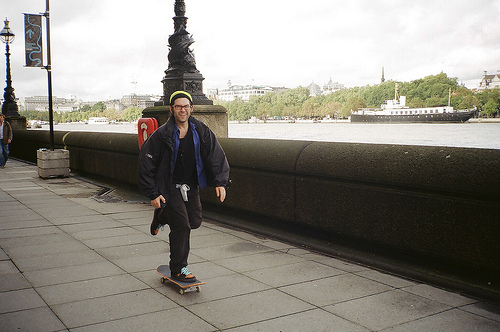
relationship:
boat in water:
[351, 81, 480, 124] [31, 123, 499, 151]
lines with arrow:
[25, 14, 45, 67] [26, 28, 35, 42]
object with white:
[137, 118, 159, 150] [139, 124, 150, 143]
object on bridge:
[137, 118, 159, 150] [1, 131, 500, 331]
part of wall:
[297, 140, 499, 300] [10, 132, 499, 299]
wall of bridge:
[10, 132, 499, 299] [1, 131, 500, 331]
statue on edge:
[160, 0, 206, 102] [0, 121, 499, 151]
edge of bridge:
[0, 121, 499, 151] [1, 131, 500, 331]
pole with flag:
[44, 0, 58, 150] [25, 14, 45, 67]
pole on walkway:
[44, 0, 58, 150] [0, 156, 499, 332]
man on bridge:
[137, 90, 231, 295] [1, 131, 500, 331]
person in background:
[0, 111, 13, 168] [0, 1, 499, 168]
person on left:
[0, 111, 13, 168] [1, 0, 143, 331]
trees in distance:
[299, 70, 500, 117] [0, 2, 499, 120]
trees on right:
[299, 70, 500, 117] [309, 1, 499, 331]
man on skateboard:
[137, 90, 231, 295] [156, 264, 206, 296]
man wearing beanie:
[137, 90, 231, 295] [168, 89, 194, 103]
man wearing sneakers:
[137, 90, 231, 295] [150, 206, 197, 283]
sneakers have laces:
[150, 206, 197, 283] [177, 266, 193, 276]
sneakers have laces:
[150, 206, 197, 283] [154, 221, 166, 231]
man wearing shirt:
[137, 90, 231, 295] [169, 124, 208, 191]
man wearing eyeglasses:
[137, 90, 231, 295] [172, 104, 192, 110]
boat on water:
[351, 81, 480, 124] [31, 123, 499, 151]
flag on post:
[25, 14, 45, 67] [44, 0, 58, 150]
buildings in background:
[1, 66, 499, 126] [0, 1, 499, 168]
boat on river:
[351, 81, 480, 124] [31, 123, 499, 151]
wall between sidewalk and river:
[10, 132, 499, 299] [0, 122, 499, 313]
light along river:
[0, 17, 27, 134] [31, 123, 499, 151]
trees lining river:
[18, 72, 499, 122] [31, 123, 499, 151]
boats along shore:
[53, 114, 350, 124] [24, 110, 498, 123]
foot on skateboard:
[169, 262, 200, 284] [156, 264, 206, 296]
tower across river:
[377, 62, 391, 89] [31, 123, 499, 151]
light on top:
[0, 14, 27, 131] [0, 7, 17, 57]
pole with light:
[0, 40, 25, 117] [0, 14, 27, 131]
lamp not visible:
[159, 0, 198, 44] [1, 0, 499, 331]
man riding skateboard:
[137, 90, 231, 295] [156, 264, 206, 296]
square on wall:
[137, 118, 159, 150] [10, 132, 499, 299]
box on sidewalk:
[37, 148, 70, 179] [0, 156, 499, 332]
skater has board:
[137, 90, 231, 295] [156, 264, 206, 296]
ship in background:
[351, 81, 480, 124] [0, 1, 499, 168]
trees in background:
[18, 72, 499, 122] [0, 1, 499, 168]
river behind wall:
[31, 123, 499, 151] [10, 132, 499, 299]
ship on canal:
[351, 81, 480, 124] [31, 123, 499, 151]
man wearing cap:
[137, 90, 231, 295] [168, 89, 194, 103]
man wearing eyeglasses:
[137, 90, 231, 295] [172, 103, 193, 111]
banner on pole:
[25, 14, 45, 67] [44, 0, 58, 150]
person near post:
[0, 111, 13, 168] [0, 17, 27, 134]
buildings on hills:
[1, 66, 499, 126] [0, 78, 499, 109]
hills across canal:
[0, 78, 499, 109] [31, 123, 499, 151]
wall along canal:
[10, 132, 499, 299] [31, 123, 499, 151]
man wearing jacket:
[137, 90, 231, 295] [137, 117, 230, 198]